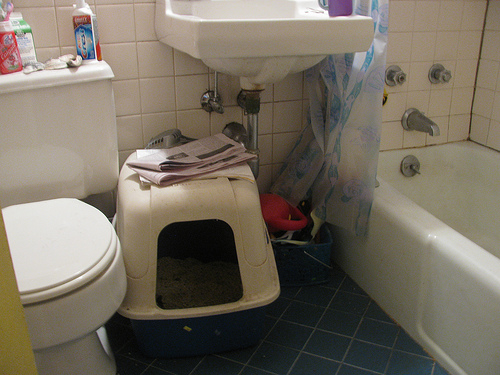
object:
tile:
[245, 339, 305, 374]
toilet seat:
[0, 195, 128, 374]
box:
[113, 149, 281, 320]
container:
[1, 20, 23, 74]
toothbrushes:
[2, 1, 17, 21]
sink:
[155, 0, 375, 93]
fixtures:
[384, 63, 452, 177]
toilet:
[2, 59, 122, 374]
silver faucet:
[400, 107, 440, 137]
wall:
[1, 0, 468, 142]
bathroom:
[0, 0, 497, 373]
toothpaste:
[70, 0, 97, 60]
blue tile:
[101, 258, 458, 375]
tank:
[0, 58, 122, 202]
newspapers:
[124, 133, 257, 186]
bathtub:
[337, 140, 500, 375]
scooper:
[145, 128, 198, 149]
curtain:
[271, 0, 390, 243]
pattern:
[326, 93, 343, 134]